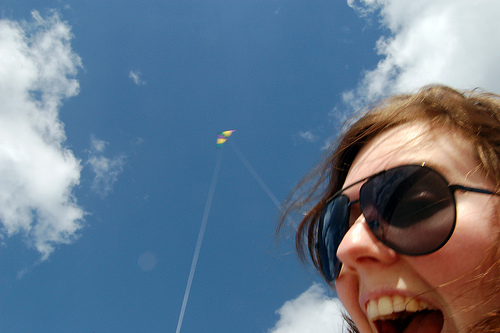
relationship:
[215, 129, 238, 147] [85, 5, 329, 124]
kite in sky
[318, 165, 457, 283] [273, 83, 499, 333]
glasses are on woman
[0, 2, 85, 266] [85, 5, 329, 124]
cloud in sky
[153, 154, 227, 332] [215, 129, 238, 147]
string attached to kite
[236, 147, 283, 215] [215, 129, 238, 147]
string attached to kite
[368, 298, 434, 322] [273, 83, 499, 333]
teeth are part of woman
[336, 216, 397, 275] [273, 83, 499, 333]
nose part of woman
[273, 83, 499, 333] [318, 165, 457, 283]
woman wearing glasses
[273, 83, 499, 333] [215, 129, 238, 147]
woman watching kite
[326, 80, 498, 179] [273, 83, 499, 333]
har part of woman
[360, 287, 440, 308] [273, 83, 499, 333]
lips are part of woman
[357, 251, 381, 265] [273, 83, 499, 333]
nostril part of woman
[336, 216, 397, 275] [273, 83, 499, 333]
nose on woman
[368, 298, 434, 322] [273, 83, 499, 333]
teeth are on woman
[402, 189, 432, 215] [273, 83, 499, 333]
eye on woman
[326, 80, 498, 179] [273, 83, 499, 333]
har on woman